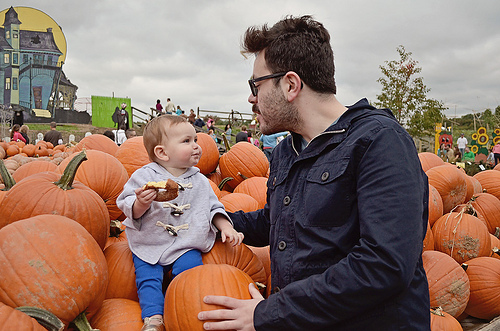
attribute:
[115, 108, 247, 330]
infant — sitting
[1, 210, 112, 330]
pumpkin — dirty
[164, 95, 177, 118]
man — standing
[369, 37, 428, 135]
tree — tall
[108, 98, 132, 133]
decoration — seasonal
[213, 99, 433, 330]
jacket — blue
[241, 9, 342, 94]
hair — dark, brown